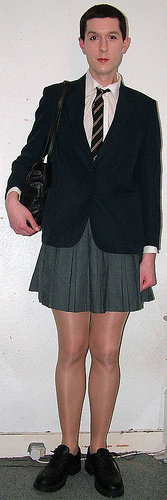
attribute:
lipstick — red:
[97, 57, 110, 64]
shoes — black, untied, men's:
[32, 444, 125, 499]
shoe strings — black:
[45, 449, 119, 473]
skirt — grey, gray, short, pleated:
[28, 219, 155, 314]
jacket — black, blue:
[4, 73, 162, 255]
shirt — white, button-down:
[6, 69, 159, 256]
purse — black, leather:
[20, 80, 69, 229]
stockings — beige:
[52, 309, 129, 455]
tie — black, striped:
[89, 86, 112, 163]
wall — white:
[1, 1, 166, 433]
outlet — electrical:
[29, 441, 46, 459]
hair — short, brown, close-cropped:
[79, 4, 127, 43]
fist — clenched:
[137, 253, 157, 293]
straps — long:
[39, 80, 70, 162]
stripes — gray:
[92, 93, 104, 161]